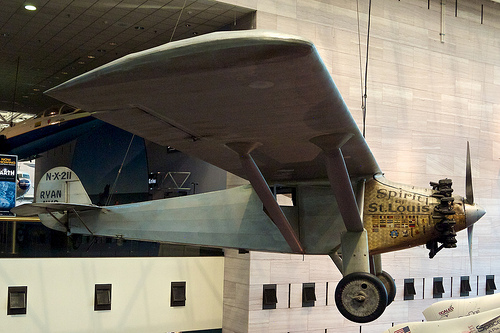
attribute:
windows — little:
[0, 276, 190, 314]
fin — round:
[27, 166, 92, 201]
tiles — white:
[394, 63, 439, 116]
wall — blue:
[34, 127, 148, 203]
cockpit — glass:
[32, 102, 73, 117]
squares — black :
[3, 276, 201, 316]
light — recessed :
[17, 2, 38, 12]